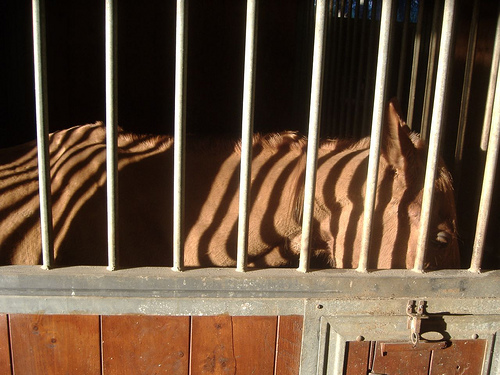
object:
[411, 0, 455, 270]
bar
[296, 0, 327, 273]
metal bar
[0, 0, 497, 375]
stall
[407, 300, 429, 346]
latch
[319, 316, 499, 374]
door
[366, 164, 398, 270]
shadow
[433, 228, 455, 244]
eye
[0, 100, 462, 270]
horse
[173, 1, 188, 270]
bar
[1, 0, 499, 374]
enclosure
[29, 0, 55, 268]
bar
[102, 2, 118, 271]
bar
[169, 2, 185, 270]
bar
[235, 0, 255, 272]
bar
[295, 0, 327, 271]
bar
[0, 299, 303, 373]
wall